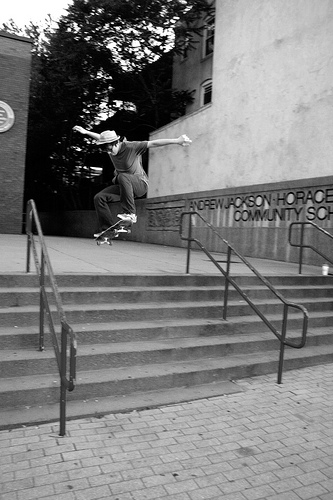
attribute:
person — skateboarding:
[69, 121, 195, 250]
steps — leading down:
[0, 272, 333, 427]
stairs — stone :
[133, 286, 210, 343]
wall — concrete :
[151, 128, 297, 255]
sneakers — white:
[114, 211, 143, 225]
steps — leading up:
[2, 275, 332, 284]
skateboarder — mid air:
[69, 118, 190, 232]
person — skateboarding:
[71, 124, 194, 221]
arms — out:
[70, 121, 185, 148]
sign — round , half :
[1, 94, 16, 139]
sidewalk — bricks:
[0, 361, 332, 498]